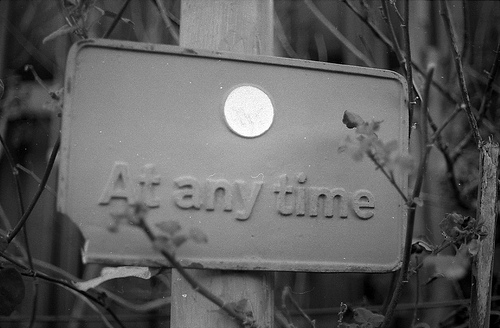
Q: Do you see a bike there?
A: No, there are no bikes.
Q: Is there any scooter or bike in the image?
A: No, there are no bikes or scooters.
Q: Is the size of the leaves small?
A: Yes, the leaves are small.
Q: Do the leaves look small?
A: Yes, the leaves are small.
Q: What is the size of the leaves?
A: The leaves are small.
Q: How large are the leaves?
A: The leaves are small.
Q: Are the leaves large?
A: No, the leaves are small.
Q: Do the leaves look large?
A: No, the leaves are small.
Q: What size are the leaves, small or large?
A: The leaves are small.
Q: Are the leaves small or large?
A: The leaves are small.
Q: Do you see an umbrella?
A: No, there are no umbrellas.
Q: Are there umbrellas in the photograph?
A: No, there are no umbrellas.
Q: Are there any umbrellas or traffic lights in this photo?
A: No, there are no umbrellas or traffic lights.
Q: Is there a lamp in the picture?
A: No, there are no lamps.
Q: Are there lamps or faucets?
A: No, there are no lamps or faucets.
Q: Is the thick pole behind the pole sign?
A: Yes, the pole is behind the sign.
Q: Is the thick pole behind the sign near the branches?
A: Yes, the pole is behind the sign.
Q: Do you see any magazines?
A: No, there are no magazines.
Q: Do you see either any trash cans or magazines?
A: No, there are no magazines or trash cans.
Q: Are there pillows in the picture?
A: No, there are no pillows.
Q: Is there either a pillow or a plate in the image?
A: No, there are no pillows or plates.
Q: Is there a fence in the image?
A: No, there are no fences.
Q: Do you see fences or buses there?
A: No, there are no fences or buses.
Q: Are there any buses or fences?
A: No, there are no fences or buses.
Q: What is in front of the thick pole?
A: The sign is in front of the pole.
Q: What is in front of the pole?
A: The sign is in front of the pole.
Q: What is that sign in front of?
A: The sign is in front of the pole.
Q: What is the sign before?
A: The sign is in front of the pole.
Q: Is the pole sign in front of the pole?
A: Yes, the sign is in front of the pole.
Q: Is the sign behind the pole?
A: No, the sign is in front of the pole.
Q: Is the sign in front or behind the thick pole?
A: The sign is in front of the pole.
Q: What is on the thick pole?
A: The sign is on the pole.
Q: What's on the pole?
A: The sign is on the pole.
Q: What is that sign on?
A: The sign is on the pole.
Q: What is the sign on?
A: The sign is on the pole.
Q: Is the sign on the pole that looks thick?
A: Yes, the sign is on the pole.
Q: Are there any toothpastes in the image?
A: No, there are no toothpastes.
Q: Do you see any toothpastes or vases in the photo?
A: No, there are no toothpastes or vases.